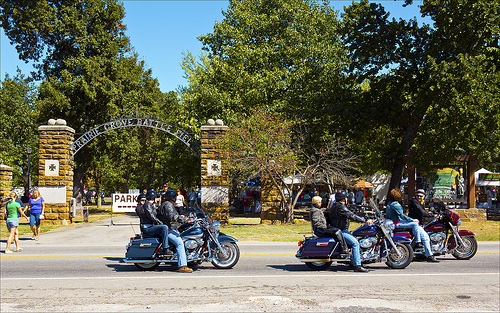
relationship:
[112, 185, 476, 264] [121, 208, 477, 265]
group of bikes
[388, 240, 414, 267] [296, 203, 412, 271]
front wheel of bike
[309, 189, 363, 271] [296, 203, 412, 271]
people are sitting on bike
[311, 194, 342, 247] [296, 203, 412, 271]
lady sitting on bike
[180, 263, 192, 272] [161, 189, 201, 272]
shoe of person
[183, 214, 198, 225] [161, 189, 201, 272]
hand of person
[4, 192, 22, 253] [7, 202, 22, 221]
girl dressed in shirt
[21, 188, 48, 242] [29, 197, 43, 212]
girl dressed in shirt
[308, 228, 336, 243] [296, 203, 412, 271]
saddlebag on bike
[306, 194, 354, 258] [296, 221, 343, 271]
lady sitting on back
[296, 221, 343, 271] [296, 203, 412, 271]
back of bike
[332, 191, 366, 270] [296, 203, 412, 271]
man on bike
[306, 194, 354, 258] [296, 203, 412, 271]
lady on bike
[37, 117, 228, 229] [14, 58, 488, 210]
entry way into park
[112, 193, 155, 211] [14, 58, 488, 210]
parking sign at park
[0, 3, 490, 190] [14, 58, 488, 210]
trees at park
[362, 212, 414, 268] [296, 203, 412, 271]
front end of bike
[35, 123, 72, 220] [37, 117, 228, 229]
column of entrance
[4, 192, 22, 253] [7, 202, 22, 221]
woman wearing shirt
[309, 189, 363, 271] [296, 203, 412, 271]
people on bike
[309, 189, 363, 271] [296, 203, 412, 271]
people are on bike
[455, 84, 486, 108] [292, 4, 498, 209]
leaves of tree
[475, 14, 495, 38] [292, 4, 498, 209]
leaves of tree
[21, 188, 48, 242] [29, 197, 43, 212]
girl wearing shirt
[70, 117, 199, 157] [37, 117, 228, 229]
sign over entrance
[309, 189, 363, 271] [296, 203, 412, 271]
people are riding bike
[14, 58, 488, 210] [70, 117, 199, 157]
park has sign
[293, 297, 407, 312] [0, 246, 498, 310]
grease stain on road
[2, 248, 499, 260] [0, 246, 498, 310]
paint on road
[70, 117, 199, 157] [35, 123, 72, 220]
sign on column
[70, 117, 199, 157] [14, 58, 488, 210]
sign for park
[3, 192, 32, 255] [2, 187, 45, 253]
each other are walking toward each other